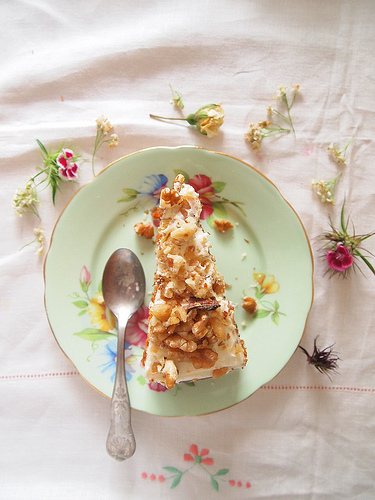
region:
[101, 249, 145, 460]
the spoon is on the plate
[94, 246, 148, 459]
the spoon is made of silver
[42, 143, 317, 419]
the dish is green with gold trim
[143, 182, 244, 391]
a pastry is on the plate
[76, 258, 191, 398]
the plate has a flower motif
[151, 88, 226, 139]
a flower is on the tablecloth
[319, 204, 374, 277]
a flower is on the tablecloth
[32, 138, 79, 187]
a flower is on the tablecloth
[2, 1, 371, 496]
the tablecloth is white in color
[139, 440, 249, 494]
the tablecloth has a flower motic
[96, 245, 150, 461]
not so shiny silver spoon.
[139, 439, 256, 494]
Hand stitched flowers on a table cloth.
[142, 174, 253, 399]
Cheese cake with nuts on top.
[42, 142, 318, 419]
A white china plate with flowers on it.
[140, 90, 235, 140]
A yellow flower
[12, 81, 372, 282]
Flower surounding the top part of a plate.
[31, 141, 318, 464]
A China plate with cheese cake on it with a spoon.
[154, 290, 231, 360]
Walnuts and other nuts.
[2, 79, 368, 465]
Live flowers used to docorate a table.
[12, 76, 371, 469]
A white table cloth under a plate and flowers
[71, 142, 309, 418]
Food on the plate.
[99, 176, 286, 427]
Dessert on the plate.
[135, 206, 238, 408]
Nuts on the cake.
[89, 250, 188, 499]
Spoon on the plate.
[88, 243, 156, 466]
Silver spoon on the plate.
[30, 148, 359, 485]
Floral plate on the table.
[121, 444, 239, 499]
Flower on the table cloth.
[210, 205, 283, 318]
Crumbs on the plate.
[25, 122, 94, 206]
Real flower on the table.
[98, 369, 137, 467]
Design on the handle.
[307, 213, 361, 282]
A purple flower is next to the plate.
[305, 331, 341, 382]
A hairy looking tuft is next to the plate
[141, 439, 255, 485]
A flower pattern is on the tablecloth.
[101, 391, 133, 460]
A spoon handle hangs past the edge of the plate.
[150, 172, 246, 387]
A piece of pie is on the plate.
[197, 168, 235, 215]
A flower pattern is on the plate.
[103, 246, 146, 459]
A spoon is o the plate.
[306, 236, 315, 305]
The plate has a gold rim.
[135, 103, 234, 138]
A rose color flower is on the table.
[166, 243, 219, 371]
The pie has some nuts on it.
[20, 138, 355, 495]
A slice of pie on a plate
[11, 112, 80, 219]
A pink flower on the table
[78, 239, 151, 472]
A spoon on the table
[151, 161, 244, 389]
A slice of pie with pecans on top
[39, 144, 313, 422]
The plate is green with flower's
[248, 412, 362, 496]
The table cloth is white with flowers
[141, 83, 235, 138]
A small yellow rose on the table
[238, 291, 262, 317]
A pecan on the plate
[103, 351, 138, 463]
The edge of the spoon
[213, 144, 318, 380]
The edge of the plate is gold